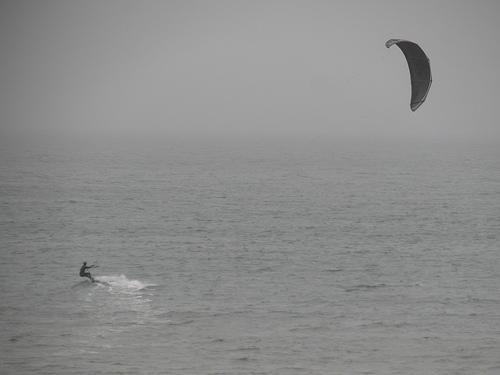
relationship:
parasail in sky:
[384, 38, 434, 111] [1, 1, 498, 150]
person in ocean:
[78, 261, 95, 282] [1, 144, 500, 374]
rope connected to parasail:
[92, 44, 417, 269] [384, 38, 434, 111]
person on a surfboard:
[78, 261, 95, 282] [93, 277, 108, 287]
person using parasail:
[78, 261, 95, 282] [384, 38, 434, 111]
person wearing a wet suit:
[78, 261, 95, 282] [78, 265, 92, 278]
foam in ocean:
[90, 273, 157, 292] [1, 144, 500, 374]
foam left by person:
[90, 273, 157, 292] [78, 261, 95, 282]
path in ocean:
[111, 285, 151, 327] [1, 144, 500, 374]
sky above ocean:
[1, 1, 498, 150] [1, 144, 500, 374]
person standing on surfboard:
[78, 261, 95, 282] [93, 277, 108, 287]